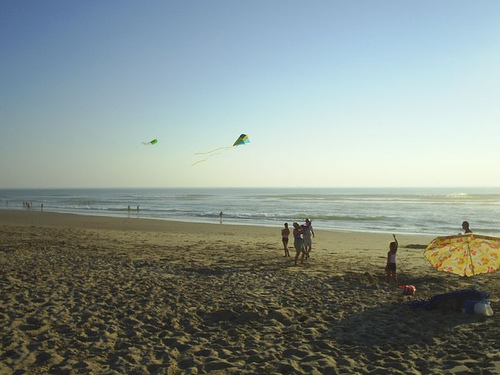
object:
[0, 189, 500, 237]
ocean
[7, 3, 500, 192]
sky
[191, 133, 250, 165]
kite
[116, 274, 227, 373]
footprints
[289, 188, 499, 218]
water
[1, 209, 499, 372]
beach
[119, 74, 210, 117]
cloud